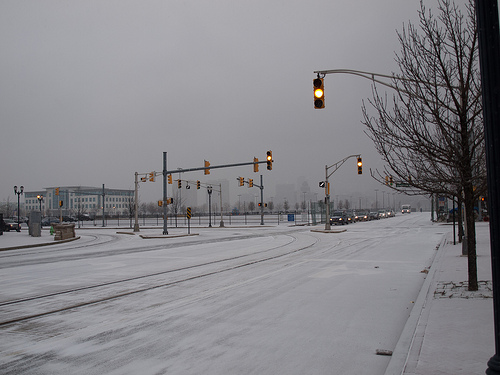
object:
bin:
[50, 223, 75, 241]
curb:
[0, 229, 75, 249]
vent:
[376, 349, 392, 356]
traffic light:
[357, 157, 362, 174]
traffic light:
[266, 150, 272, 170]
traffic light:
[204, 159, 211, 174]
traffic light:
[168, 174, 172, 184]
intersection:
[4, 219, 481, 270]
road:
[0, 215, 500, 375]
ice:
[0, 251, 494, 375]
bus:
[401, 205, 411, 214]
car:
[345, 212, 356, 223]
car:
[354, 208, 370, 221]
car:
[370, 212, 379, 221]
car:
[378, 210, 388, 219]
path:
[388, 224, 499, 372]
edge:
[382, 322, 409, 374]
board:
[166, 159, 273, 174]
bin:
[288, 214, 295, 222]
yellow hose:
[14, 186, 105, 232]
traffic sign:
[187, 207, 192, 234]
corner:
[141, 235, 148, 239]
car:
[329, 210, 348, 225]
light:
[313, 78, 326, 109]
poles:
[14, 185, 64, 232]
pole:
[325, 165, 332, 230]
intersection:
[179, 193, 352, 279]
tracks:
[0, 230, 317, 375]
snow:
[0, 215, 497, 375]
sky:
[2, 0, 489, 205]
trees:
[359, 0, 492, 291]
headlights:
[330, 218, 343, 221]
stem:
[459, 114, 478, 291]